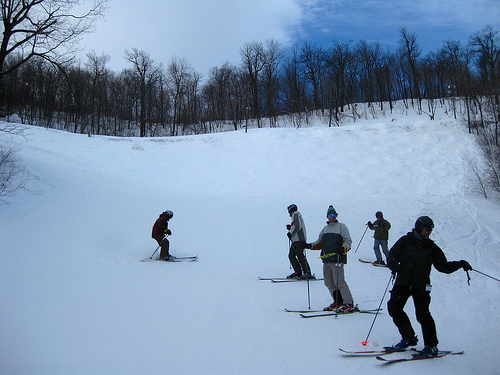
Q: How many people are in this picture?
A: 5.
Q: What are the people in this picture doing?
A: Skiing.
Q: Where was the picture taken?
A: In the snow.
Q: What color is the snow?
A: White.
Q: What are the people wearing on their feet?
A: Skis.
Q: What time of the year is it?
A: Winter.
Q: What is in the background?
A: Trees.